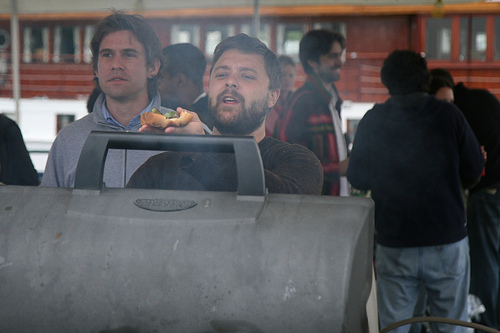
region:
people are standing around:
[82, 2, 489, 270]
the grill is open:
[14, 90, 383, 317]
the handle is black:
[34, 105, 281, 206]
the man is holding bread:
[120, 73, 237, 155]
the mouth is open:
[197, 88, 250, 107]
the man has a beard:
[189, 69, 282, 144]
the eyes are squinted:
[202, 49, 265, 86]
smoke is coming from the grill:
[127, 10, 257, 226]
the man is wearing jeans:
[365, 214, 478, 329]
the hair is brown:
[200, 15, 282, 100]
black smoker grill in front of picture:
[41, 126, 453, 330]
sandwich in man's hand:
[135, 96, 192, 143]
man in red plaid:
[296, 22, 349, 175]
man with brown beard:
[208, 38, 288, 155]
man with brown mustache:
[196, 34, 291, 159]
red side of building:
[379, 6, 494, 66]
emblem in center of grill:
[123, 185, 219, 245]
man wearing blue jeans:
[386, 228, 497, 318]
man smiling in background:
[296, 25, 366, 88]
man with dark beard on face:
[304, 27, 374, 112]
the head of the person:
[95, 25, 150, 96]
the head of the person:
[209, 37, 269, 129]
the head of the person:
[155, 43, 204, 105]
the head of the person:
[275, 56, 297, 93]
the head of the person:
[298, 31, 343, 78]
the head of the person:
[382, 49, 426, 100]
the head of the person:
[432, 80, 454, 103]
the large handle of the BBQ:
[72, 125, 265, 197]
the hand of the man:
[139, 110, 209, 137]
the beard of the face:
[205, 87, 265, 129]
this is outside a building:
[15, 30, 476, 296]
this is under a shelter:
[55, 12, 460, 295]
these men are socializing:
[311, 26, 466, 223]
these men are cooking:
[76, 60, 309, 320]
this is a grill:
[21, 132, 269, 292]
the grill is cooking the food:
[8, 130, 286, 321]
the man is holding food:
[111, 90, 246, 170]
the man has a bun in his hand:
[136, 112, 222, 137]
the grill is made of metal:
[8, 171, 264, 307]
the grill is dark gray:
[33, 175, 283, 330]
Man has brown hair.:
[216, 33, 279, 71]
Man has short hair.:
[216, 33, 271, 60]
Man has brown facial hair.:
[208, 84, 251, 120]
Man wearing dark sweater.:
[273, 153, 299, 188]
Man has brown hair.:
[135, 28, 168, 56]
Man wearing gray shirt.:
[40, 131, 90, 171]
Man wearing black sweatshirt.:
[377, 116, 420, 206]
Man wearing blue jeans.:
[384, 242, 444, 294]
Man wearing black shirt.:
[466, 83, 491, 137]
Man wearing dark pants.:
[476, 228, 494, 276]